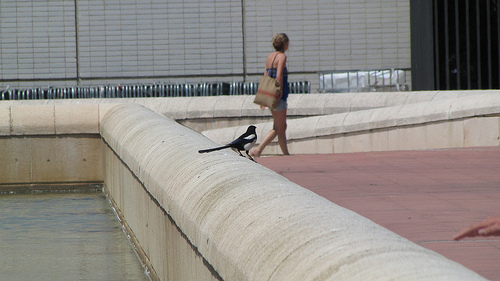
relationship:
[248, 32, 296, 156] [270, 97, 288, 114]
person wearing skirt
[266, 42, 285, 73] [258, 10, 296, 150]
back of a person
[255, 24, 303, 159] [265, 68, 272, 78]
person wearing a top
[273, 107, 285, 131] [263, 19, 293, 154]
thigh of a person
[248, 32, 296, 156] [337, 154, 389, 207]
person walking on ground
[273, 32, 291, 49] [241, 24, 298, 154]
head of person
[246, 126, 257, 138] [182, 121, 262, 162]
head of bird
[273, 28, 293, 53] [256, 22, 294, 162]
head of woman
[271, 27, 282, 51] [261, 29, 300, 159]
hair of a woman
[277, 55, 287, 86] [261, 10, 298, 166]
arm of a woman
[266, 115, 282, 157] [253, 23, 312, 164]
legs of a woman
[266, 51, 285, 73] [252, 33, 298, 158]
back of a woman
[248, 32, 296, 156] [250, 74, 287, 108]
person holding a bag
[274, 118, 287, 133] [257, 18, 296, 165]
knees of a woman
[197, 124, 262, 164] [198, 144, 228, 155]
bird has tail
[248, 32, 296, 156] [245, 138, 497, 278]
person on sidewalk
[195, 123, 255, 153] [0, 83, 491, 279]
brick in a building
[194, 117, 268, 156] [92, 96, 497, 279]
bird on a ledge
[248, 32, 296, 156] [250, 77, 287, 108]
person carrying a bag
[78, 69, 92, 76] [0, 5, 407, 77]
brick on wall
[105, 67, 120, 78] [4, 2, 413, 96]
brick on wall